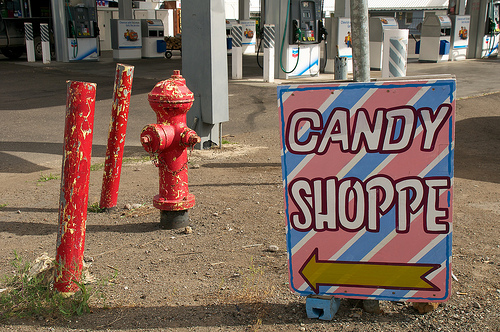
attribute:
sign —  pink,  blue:
[238, 59, 485, 323]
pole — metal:
[44, 67, 105, 297]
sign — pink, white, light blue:
[274, 69, 465, 308]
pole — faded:
[92, 50, 142, 224]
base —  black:
[158, 205, 191, 232]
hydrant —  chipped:
[139, 67, 201, 230]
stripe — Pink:
[280, 83, 450, 300]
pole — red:
[44, 74, 99, 297]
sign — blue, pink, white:
[204, 29, 471, 329]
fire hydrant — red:
[141, 66, 205, 211]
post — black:
[158, 210, 191, 227]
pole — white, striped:
[227, 20, 244, 85]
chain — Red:
[150, 156, 191, 171]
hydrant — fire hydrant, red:
[142, 68, 197, 229]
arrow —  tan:
[292, 248, 446, 294]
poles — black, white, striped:
[23, 19, 52, 56]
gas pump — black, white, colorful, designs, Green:
[264, 0, 324, 76]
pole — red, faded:
[55, 77, 95, 295]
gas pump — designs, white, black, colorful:
[276, 29, 337, 82]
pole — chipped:
[91, 55, 134, 220]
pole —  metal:
[67, 85, 87, 295]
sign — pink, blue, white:
[279, 80, 456, 300]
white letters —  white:
[284, 104, 458, 152]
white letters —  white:
[283, 175, 451, 232]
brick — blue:
[299, 304, 327, 329]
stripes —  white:
[333, 236, 379, 264]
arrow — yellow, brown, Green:
[298, 245, 440, 296]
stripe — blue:
[273, 76, 454, 304]